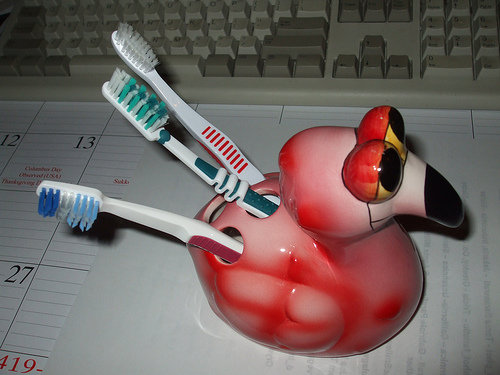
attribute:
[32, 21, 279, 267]
toothbrushes — bristled, grouped, white, blue, designed, green, gripped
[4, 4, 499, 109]
keyboard — tan, white, gray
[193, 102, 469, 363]
holder — bird shaped, red, pink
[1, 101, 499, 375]
calendar — white, large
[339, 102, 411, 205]
eyes — yellow, black, red